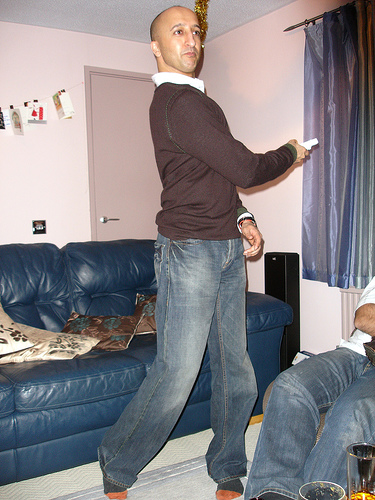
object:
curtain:
[301, 0, 375, 289]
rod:
[283, 0, 373, 31]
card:
[52, 88, 75, 120]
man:
[96, 5, 309, 500]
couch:
[0, 238, 294, 487]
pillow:
[61, 310, 146, 352]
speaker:
[264, 252, 300, 373]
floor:
[152, 470, 199, 500]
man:
[244, 276, 375, 500]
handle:
[99, 216, 119, 223]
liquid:
[348, 492, 374, 499]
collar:
[151, 72, 204, 94]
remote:
[299, 138, 318, 151]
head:
[150, 5, 202, 73]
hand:
[288, 139, 310, 165]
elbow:
[354, 303, 375, 337]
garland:
[194, 0, 209, 45]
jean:
[97, 232, 258, 488]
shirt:
[149, 81, 294, 241]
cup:
[346, 442, 375, 500]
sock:
[216, 479, 244, 500]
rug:
[0, 421, 262, 500]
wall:
[1, 150, 84, 186]